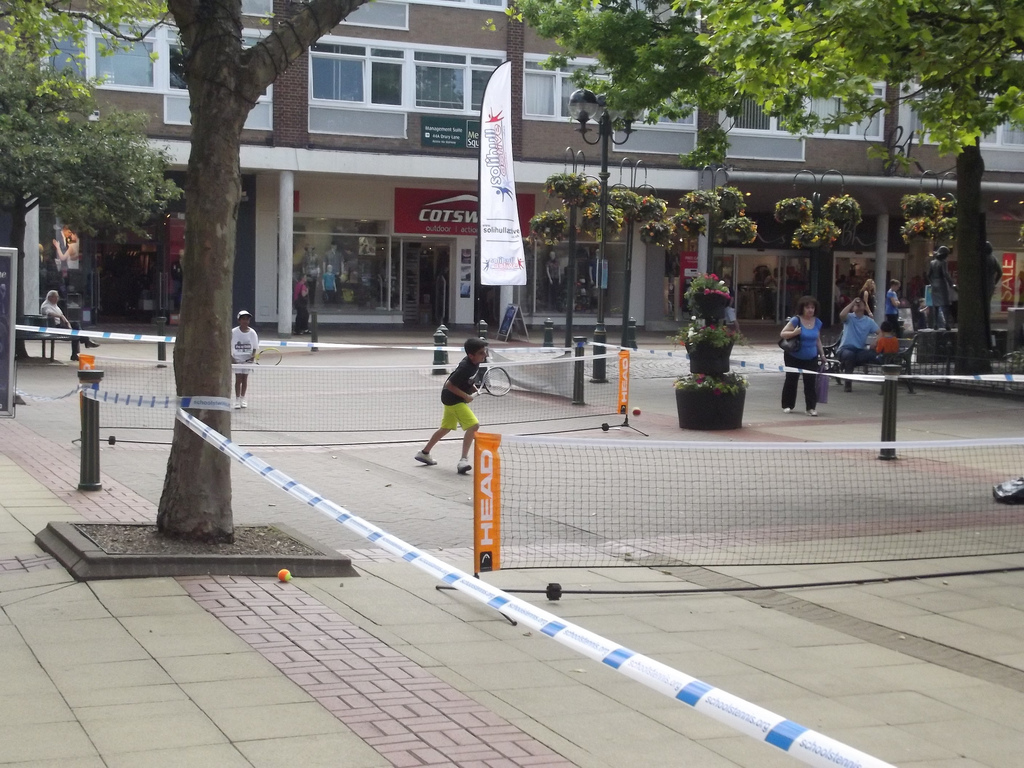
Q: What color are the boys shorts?
A: Yellow.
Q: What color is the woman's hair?
A: Brown.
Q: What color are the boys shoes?
A: White.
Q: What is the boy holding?
A: Tennis racket.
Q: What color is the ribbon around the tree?
A: White and blue.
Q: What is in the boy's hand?
A: Tennis racket.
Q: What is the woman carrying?
A: Purse.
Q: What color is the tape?
A: Blue and white.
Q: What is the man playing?
A: Tennis.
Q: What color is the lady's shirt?
A: Blue.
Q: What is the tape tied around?
A: Tree.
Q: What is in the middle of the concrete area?
A: Flowers.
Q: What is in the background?
A: Storefront.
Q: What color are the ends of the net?
A: Orange.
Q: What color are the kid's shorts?
A: Yellow.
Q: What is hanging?
A: Potted plants.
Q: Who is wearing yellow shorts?
A: A boy.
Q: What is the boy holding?
A: A tennis racket.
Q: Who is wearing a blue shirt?
A: One lady.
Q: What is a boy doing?
A: Playing tennis.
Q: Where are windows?
A: On a building.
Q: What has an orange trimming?
A: A net.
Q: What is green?
A: Leaves of a tree.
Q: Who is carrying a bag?
A: Woman in blue.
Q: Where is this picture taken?
A: Tennis court.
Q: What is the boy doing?
A: Playing tennis.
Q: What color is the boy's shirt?
A: Blue.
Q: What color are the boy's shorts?
A: Yellow.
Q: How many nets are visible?
A: Two.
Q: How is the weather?
A: Clear.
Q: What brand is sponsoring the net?
A: Head.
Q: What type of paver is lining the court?
A: Brick.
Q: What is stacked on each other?
A: Planters.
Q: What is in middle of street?
A: Tennis net.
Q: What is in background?
A: Building.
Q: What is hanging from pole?
A: Ad banner.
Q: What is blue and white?
A: Tennis net.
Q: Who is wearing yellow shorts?
A: A boy.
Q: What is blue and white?
A: Plastic tape.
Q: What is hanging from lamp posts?
A: Planter baskets.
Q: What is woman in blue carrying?
A: Purse and shopping bag.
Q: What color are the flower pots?
A: Black.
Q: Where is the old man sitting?
A: On a bench.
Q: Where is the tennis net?
A: In the courtyard.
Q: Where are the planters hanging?
A: Off of poles.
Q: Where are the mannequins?
A: In the storefront window.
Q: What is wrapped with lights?
A: The tree trunk.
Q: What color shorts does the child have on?
A: Yellow.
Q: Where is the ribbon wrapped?
A: Around the tree trunk.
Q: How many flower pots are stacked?
A: Three.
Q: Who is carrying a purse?
A: The woman in a blue shirt.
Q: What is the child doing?
A: Playing tennis.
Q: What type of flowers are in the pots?
A: No indication.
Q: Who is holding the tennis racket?
A: Boy.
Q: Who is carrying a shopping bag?
A: Woman on tennis court.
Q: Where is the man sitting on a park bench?
A: In the background, to the right.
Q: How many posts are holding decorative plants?
A: Four.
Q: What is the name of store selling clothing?
A: No indication.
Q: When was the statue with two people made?
A: No indication.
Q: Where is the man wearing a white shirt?
A: In the background, left side.